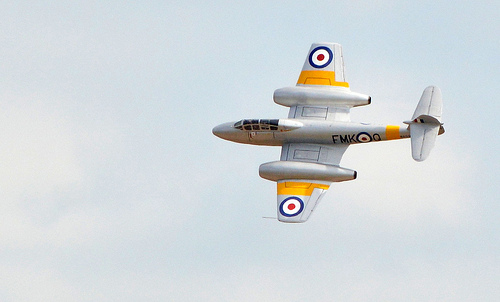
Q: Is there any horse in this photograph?
A: No, there are no horses.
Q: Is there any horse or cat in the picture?
A: No, there are no horses or cats.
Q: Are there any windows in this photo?
A: Yes, there is a window.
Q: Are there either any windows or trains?
A: Yes, there is a window.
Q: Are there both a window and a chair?
A: No, there is a window but no chairs.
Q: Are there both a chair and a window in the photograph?
A: No, there is a window but no chairs.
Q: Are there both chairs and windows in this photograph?
A: No, there is a window but no chairs.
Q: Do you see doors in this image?
A: No, there are no doors.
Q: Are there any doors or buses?
A: No, there are no doors or buses.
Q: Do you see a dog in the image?
A: No, there are no dogs.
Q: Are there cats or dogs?
A: No, there are no dogs or cats.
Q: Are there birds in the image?
A: No, there are no birds.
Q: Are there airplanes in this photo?
A: Yes, there is an airplane.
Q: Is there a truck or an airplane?
A: Yes, there is an airplane.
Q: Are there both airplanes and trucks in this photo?
A: No, there is an airplane but no trucks.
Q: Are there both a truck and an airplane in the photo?
A: No, there is an airplane but no trucks.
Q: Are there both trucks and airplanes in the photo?
A: No, there is an airplane but no trucks.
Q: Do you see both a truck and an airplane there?
A: No, there is an airplane but no trucks.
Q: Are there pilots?
A: No, there are no pilots.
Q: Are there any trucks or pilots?
A: No, there are no pilots or trucks.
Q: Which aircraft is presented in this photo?
A: The aircraft is an airplane.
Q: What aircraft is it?
A: The aircraft is an airplane.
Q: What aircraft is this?
A: This is an airplane.